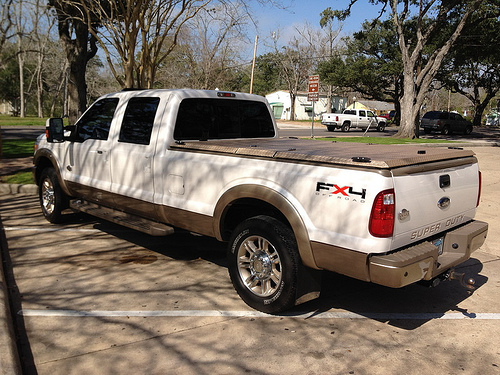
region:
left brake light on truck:
[367, 185, 397, 248]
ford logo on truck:
[433, 192, 459, 214]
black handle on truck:
[437, 172, 462, 192]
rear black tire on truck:
[223, 206, 299, 318]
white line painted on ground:
[18, 300, 268, 331]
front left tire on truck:
[34, 165, 67, 237]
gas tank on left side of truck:
[166, 169, 189, 198]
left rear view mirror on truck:
[44, 111, 71, 148]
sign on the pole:
[307, 70, 326, 104]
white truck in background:
[322, 101, 390, 131]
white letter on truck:
[422, 225, 429, 237]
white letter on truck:
[428, 223, 435, 234]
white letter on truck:
[433, 222, 443, 235]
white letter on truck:
[444, 216, 450, 226]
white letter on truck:
[449, 215, 456, 228]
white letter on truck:
[455, 213, 460, 225]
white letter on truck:
[457, 212, 467, 224]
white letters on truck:
[411, 211, 465, 241]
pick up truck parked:
[13, 62, 473, 322]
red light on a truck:
[372, 183, 399, 238]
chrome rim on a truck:
[232, 232, 283, 297]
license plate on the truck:
[424, 233, 459, 267]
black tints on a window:
[111, 92, 173, 157]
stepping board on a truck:
[61, 189, 177, 251]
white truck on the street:
[328, 98, 388, 135]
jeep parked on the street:
[412, 100, 473, 145]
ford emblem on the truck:
[434, 196, 457, 213]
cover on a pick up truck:
[174, 123, 479, 185]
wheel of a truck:
[220, 218, 310, 318]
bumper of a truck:
[383, 213, 499, 291]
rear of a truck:
[385, 138, 487, 234]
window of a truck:
[118, 82, 163, 147]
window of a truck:
[168, 83, 277, 142]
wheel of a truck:
[28, 163, 65, 224]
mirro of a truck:
[42, 106, 74, 151]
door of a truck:
[73, 108, 115, 185]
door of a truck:
[112, 128, 160, 215]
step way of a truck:
[68, 182, 174, 240]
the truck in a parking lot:
[32, 88, 488, 313]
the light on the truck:
[368, 188, 395, 238]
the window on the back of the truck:
[172, 98, 275, 139]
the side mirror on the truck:
[45, 117, 77, 142]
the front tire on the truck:
[37, 167, 70, 222]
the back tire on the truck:
[227, 213, 309, 314]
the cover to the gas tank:
[167, 173, 184, 194]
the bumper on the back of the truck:
[367, 219, 488, 289]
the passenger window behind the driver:
[118, 96, 160, 146]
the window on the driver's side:
[69, 97, 119, 140]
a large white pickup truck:
[26, 78, 491, 316]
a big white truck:
[28, 84, 493, 315]